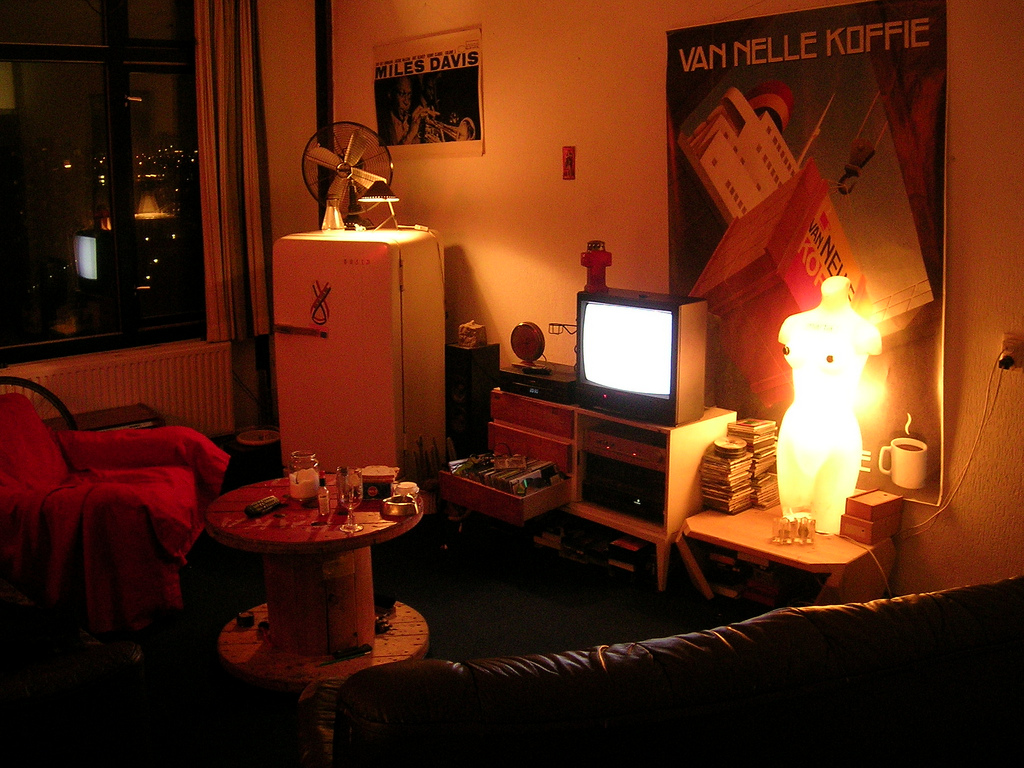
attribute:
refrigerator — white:
[261, 219, 434, 487]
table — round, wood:
[203, 463, 432, 693]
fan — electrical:
[300, 121, 404, 236]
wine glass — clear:
[335, 465, 372, 530]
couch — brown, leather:
[334, 565, 991, 753]